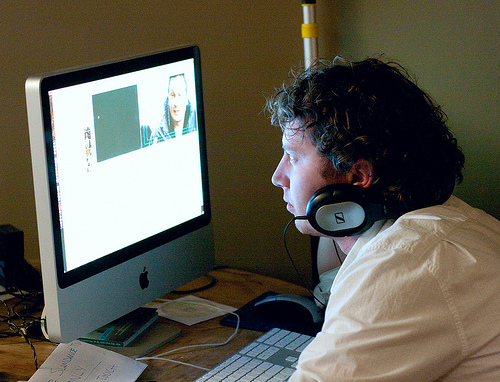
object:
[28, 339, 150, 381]
paper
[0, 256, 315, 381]
desk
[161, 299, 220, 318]
cd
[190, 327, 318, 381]
keyboard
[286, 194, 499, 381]
shirt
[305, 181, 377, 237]
headphones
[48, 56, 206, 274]
computer screen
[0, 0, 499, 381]
room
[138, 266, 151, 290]
apple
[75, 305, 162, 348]
book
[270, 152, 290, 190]
nose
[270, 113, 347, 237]
face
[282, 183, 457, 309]
headphone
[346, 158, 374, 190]
ear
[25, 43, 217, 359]
monitor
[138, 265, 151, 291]
logo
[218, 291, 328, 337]
pad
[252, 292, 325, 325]
mouse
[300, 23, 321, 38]
plastic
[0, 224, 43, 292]
container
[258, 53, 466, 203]
hair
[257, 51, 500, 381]
man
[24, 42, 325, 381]
components